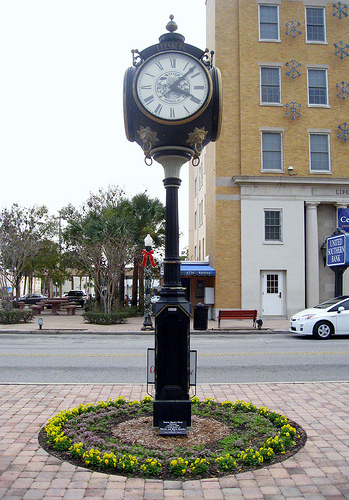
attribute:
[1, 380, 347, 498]
sidewalk — bricked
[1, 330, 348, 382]
street — paved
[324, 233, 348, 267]
sign — blue, white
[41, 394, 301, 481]
flower bed — circular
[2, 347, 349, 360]
line — yellow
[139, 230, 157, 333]
lamplight — decorated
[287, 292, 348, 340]
car — white, parked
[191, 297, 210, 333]
trash can — black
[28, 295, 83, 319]
table and seats —  in public 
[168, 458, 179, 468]
flower — yellow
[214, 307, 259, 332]
bench — red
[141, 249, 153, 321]
decorations — christmassy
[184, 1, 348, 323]
building — large, tall